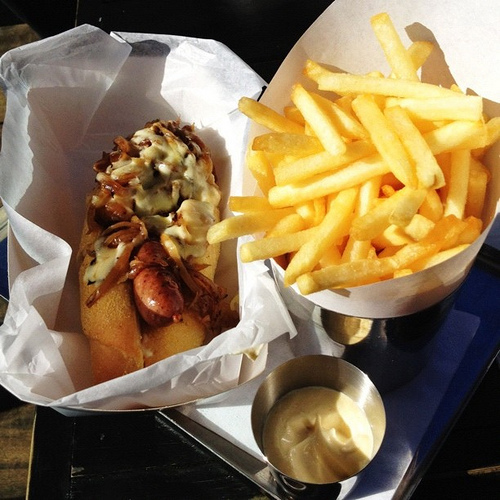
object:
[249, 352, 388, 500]
container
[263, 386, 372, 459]
sauce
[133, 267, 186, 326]
hot dog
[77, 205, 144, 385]
bun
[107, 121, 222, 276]
cheese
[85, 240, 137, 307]
onion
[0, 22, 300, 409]
paper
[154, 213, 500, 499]
tray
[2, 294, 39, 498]
table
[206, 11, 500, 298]
fries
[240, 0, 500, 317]
container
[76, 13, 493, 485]
food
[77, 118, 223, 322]
toppings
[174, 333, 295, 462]
napkin